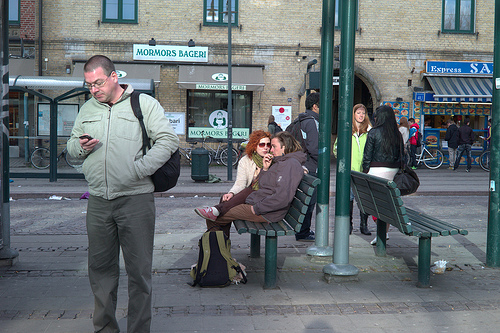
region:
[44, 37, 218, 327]
Man on the sidewalk.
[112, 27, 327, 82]
Sign on the building.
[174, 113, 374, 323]
People on the bench.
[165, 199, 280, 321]
Back pack by the bench.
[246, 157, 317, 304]
Bench on the ground.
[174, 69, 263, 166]
Window on the building.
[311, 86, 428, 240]
Woman standing in the background.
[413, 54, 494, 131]
Awning over the window.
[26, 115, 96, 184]
Bicycle in the background.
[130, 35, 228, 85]
White and green sign.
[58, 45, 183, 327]
man standing on street looking at phone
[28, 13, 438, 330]
people waiting at bus stop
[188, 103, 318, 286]
couple sitting on bench at bus stop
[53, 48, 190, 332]
man carrying black backpack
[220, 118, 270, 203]
woman with red hair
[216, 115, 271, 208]
woman with red curly hair and green scarf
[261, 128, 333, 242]
man wearing blue sweatshirt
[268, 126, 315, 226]
person wearing hooded sweatshirt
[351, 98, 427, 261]
two women waiting at bus stop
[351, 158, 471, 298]
green wooden bench at bus stop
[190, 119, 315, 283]
two people sitting on green bench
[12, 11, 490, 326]
picture taken on a city street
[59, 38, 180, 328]
man looking at cell phone in his hands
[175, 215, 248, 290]
back pack on the ground near bench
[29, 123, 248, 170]
bicycles leaning against the building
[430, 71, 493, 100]
blue and silver awning attached to building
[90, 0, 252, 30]
windows with green frames attached to brick building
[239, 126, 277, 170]
woman with bright red hair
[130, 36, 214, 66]
white sign with blue lettering over business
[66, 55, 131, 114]
mann wearing eye glasses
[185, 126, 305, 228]
people sitting on bench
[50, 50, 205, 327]
the man using the phone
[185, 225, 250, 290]
the bag on the ground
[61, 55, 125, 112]
the man wearing glasses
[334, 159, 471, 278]
the bench is empty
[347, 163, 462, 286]
the bench is green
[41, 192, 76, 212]
garbage in the street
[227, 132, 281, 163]
woman wearing sunglasses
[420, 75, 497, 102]
awning on the building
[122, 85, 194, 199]
the backpack over the shoulder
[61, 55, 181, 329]
Man wearing a gray jacket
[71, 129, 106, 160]
Phone in man's hand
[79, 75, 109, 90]
Glasses on the man's face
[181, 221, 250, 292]
Backpack on the ground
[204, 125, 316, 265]
Two people sitting on bench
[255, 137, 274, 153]
Glasses on the woman's face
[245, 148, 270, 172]
Scarf around the woman's neck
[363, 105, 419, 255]
Woman wearing a black jacket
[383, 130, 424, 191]
Bag on the woman's shoulder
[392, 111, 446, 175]
Man on a bicycle